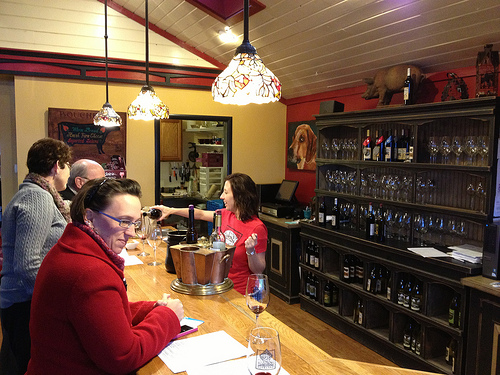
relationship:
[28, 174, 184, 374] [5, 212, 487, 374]
people standing in front of bar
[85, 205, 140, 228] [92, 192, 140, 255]
eyeglasses on face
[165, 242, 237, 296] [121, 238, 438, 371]
bucket on counter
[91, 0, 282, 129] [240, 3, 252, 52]
lamp hanging down from pole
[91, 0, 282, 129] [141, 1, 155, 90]
lamp hanging down from pole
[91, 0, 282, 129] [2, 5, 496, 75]
lamp hanging down from ceiling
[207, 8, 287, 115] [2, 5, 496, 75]
lamp hanging down from ceiling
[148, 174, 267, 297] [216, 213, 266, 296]
bartender wearing t-shirt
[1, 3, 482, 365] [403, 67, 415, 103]
bar full of bottle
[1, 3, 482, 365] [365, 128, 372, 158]
bar full of bottle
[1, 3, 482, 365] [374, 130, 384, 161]
bar full of bottle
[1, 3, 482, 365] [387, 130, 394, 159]
bar full of bottle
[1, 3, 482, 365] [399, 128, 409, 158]
bar full of bottle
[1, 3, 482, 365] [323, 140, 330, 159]
bar full of glass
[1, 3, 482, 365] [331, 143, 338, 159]
bar full of glass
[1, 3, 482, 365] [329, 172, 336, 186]
bar full of glass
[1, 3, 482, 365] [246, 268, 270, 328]
bar full of glass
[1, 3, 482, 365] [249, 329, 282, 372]
bar full of glass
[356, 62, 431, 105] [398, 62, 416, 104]
pig with bottle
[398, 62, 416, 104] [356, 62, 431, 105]
bottle in front of pig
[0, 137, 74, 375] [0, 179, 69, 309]
people wearing grey sweater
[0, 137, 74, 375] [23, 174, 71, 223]
people wearing scarf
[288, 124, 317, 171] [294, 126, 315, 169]
dog painting of dog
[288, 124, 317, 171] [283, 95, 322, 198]
dog painting against red wall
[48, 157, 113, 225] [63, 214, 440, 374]
people at bar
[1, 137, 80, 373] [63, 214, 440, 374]
people at bar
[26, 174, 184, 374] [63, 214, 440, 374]
people at bar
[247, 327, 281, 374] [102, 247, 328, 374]
glass on counter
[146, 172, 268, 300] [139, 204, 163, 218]
bartender pouring wine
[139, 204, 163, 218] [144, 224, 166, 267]
wine in glass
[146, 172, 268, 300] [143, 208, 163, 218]
bartender pouring wine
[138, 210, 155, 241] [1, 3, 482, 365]
wineglass at bar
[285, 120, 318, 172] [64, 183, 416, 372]
dog painting at a bar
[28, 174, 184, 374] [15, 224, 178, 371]
people wearing coat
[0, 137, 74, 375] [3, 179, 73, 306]
people wearing grey sweater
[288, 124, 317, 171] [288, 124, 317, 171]
dog painting in dog painting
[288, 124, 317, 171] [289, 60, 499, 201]
dog painting on wall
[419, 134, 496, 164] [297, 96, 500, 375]
glasses on shelf